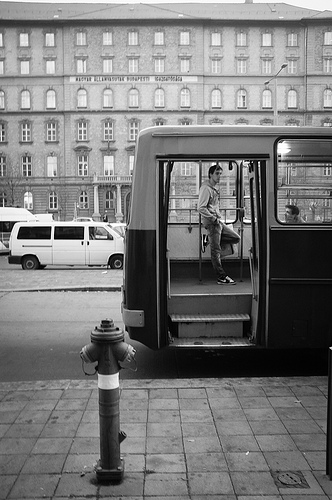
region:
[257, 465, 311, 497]
square iron grate on ground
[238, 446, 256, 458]
small piece of white paper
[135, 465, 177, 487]
small black spot on ground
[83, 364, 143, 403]
small white area on fire hydrant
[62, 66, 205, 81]
large sign on apartment building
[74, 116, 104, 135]
large window in building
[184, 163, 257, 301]
man leaning against post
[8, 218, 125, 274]
large white van parked in spot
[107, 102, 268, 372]
rear of passenger bus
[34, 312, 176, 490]
large fire hydrant on sidewalk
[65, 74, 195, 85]
The name of the building written on the building.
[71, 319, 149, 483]
Fire hydrant on the street.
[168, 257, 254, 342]
Steps going up to the bus.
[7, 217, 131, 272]
White bus in the background.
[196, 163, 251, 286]
Man leaning on the bus.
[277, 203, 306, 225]
Man sitting on bus.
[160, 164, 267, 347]
Bus door open.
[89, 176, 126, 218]
Pillars on the building.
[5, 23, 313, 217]
Lot of windows on the building.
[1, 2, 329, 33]
Roof of the building.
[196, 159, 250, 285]
man standing inside of bus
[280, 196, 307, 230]
man sitting inside of bus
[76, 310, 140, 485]
hydrant on the sidewalk beside the bus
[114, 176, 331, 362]
passenger bus at a stop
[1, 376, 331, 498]
sidewalk beside the bus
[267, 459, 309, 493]
drain hole on the sidewalk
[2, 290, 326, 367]
road the bus is traveling on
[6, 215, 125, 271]
white van parked on the other side of the bus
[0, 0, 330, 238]
large buiding on the other side of the bus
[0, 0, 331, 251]
large building with lots of windows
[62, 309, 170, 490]
fire hydrate on city street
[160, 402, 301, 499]
cement tiles on city street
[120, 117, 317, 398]
city bus waiting at bus stop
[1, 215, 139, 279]
white mini van parked on city street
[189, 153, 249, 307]
man standing on city bus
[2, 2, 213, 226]
building in the city with arched windows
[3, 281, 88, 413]
paved city street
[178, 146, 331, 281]
two people talking on city bus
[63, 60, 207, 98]
banner telling name of building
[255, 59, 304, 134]
city street light on pole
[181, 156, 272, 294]
a man on a bus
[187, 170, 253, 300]
a man standing on a bus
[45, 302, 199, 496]
a fire hydrant on a sidewalk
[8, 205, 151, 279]
a white van on the road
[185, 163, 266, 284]
a man wearing jeans leans against a pole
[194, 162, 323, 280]
two men on a bus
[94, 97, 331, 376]
a bus at the side of the road with it's door open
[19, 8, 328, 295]
a large building on the side of a road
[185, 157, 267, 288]
a man on a bus wearing a sweatshirt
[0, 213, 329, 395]
a two lane road separated by a walkway